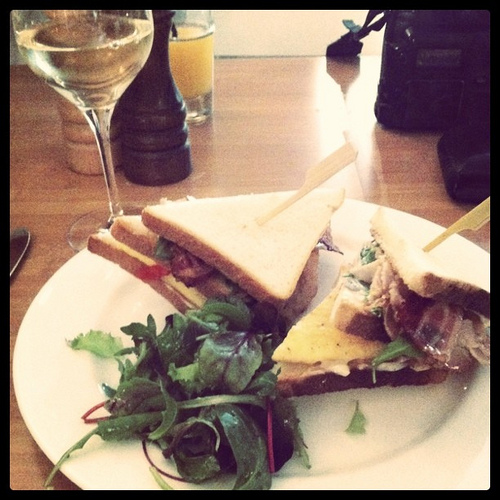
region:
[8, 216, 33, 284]
The tip of a silver knife.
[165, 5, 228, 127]
A glass with a orange drink.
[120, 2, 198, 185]
A tall black pepper mill.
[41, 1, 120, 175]
A tall salt mill.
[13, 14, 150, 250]
A tall glass with a clear beverage.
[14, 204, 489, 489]
A round white plate.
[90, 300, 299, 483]
A serving of raw vegetables.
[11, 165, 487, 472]
A sandwich cut in half.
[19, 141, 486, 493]
Sandwich served on a white plate.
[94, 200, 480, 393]
Brown crust on the pieces of bread.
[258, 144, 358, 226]
A toothpick in a sandwich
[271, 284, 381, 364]
Cheese on the sandwich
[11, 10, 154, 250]
A glass of a beverage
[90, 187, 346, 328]
A sandwich on the plate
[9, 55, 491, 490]
The table beneath the plate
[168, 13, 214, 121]
A glass of an orange liquid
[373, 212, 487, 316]
Bread on top of the sandwich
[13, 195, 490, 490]
The white plate is circular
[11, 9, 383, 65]
A wall by the table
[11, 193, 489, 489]
The plate holds the sandwiches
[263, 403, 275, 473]
red lettuce stem in the salad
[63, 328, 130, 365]
green leaf in the salad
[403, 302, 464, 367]
slice of bacon on the sandwich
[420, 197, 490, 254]
tan toothpick in the sadwich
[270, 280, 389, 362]
slice of white cheese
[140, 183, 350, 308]
triangular slice of white bread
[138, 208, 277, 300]
brown crust on the bread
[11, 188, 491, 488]
white plate under the food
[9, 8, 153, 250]
clear glass of white wine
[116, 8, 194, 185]
pepper grinder behind the glass of wine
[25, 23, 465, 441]
this is a dinner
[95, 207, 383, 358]
this is a sliced sandwich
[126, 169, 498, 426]
the sandwich is cut in half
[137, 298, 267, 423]
this is a small salad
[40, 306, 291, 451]
the salad is green and purple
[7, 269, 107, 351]
this is a dinner plate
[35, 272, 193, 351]
the dinner plate is glass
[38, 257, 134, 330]
the dinner plate is white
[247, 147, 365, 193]
this is a toothpick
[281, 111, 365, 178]
the toothpick is wooden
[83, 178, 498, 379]
two slices of sandwich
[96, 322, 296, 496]
a portion of green salad